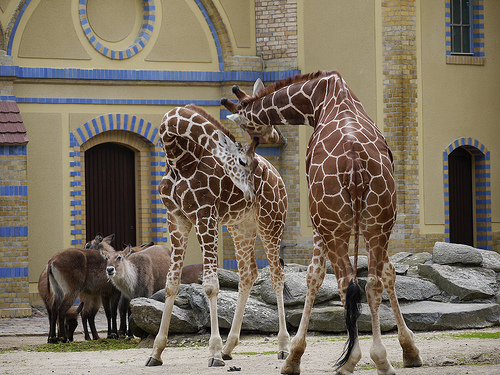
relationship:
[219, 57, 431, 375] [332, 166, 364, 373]
giraffe has tail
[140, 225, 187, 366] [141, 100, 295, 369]
leg on giraffe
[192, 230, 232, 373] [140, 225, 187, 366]
leg on leg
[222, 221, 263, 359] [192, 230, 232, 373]
leg on leg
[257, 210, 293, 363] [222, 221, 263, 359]
legs on leg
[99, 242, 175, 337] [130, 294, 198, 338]
deer standing behind rock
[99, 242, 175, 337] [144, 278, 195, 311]
deer standing behind rock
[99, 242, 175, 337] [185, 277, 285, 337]
deer standing behind rock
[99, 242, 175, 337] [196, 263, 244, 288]
deer standing behind rock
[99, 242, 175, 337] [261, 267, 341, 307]
deer standing behind rock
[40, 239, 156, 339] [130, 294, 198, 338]
deer standing behind rock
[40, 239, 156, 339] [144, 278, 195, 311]
deer standing behind rock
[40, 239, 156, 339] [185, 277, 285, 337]
deer standing behind rock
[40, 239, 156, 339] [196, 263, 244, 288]
deer standing behind rock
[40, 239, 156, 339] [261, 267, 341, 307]
deer standing behind rock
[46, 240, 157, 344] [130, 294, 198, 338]
deer standing behind rock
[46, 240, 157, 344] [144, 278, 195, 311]
deer standing behind rock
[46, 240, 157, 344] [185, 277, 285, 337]
deer standing behind rock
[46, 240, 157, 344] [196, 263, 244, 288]
deer standing behind rock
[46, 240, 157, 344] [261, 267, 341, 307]
deer standing behind rock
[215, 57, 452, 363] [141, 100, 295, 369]
giraffe near giraffe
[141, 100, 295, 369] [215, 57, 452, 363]
giraffe near giraffe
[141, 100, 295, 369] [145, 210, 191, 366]
giraffe has leg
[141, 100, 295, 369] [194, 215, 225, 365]
giraffe has leg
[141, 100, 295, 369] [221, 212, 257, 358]
giraffe has leg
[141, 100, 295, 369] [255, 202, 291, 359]
giraffe has leg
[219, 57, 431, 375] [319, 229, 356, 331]
giraffe has leg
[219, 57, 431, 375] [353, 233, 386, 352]
giraffe has leg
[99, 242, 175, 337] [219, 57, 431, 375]
deer behind giraffe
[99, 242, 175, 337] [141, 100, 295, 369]
deer behind giraffe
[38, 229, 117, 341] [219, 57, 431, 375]
deer behind giraffe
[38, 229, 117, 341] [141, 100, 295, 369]
deer behind giraffe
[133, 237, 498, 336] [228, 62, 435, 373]
rock pile behind giraffe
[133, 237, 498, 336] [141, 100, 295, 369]
rock pile behind giraffe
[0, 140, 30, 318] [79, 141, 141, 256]
wall next to door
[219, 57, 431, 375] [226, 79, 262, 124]
giraffe has ears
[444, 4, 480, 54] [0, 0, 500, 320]
window on house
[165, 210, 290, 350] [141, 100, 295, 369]
legs of giraffe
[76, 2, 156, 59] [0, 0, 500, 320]
round architecture on house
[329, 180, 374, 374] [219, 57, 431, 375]
tail of giraffe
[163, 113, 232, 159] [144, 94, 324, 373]
neck of giraffe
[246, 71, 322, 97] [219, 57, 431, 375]
mane on giraffe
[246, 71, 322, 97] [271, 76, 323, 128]
mane on neck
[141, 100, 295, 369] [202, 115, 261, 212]
giraffe with head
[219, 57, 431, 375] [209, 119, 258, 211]
giraffe with head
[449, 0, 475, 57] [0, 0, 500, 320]
window on house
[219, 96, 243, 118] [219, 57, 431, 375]
horn on giraffe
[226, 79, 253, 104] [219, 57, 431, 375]
horn on giraffe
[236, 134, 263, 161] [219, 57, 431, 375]
horn on giraffe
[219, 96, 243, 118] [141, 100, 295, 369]
horn on giraffe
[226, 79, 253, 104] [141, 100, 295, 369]
horn on giraffe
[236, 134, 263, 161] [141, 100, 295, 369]
horn on giraffe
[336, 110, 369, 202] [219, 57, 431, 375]
white lines on giraffe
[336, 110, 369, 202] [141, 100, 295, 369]
white lines on giraffe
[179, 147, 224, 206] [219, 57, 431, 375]
white lines on giraffe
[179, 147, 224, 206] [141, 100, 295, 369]
white lines on giraffe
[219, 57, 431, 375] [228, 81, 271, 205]
giraffe with head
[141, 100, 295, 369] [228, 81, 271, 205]
giraffe with head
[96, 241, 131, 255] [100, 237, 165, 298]
ears of deer